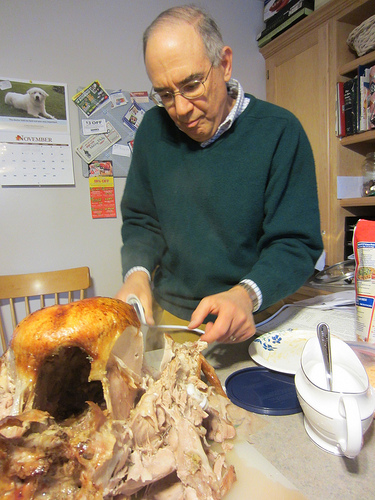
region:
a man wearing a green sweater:
[120, 5, 324, 359]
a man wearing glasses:
[117, 6, 322, 348]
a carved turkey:
[0, 295, 237, 497]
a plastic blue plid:
[225, 365, 303, 416]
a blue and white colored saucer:
[247, 328, 324, 376]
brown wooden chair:
[0, 267, 91, 351]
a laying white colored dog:
[3, 86, 56, 119]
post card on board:
[71, 68, 109, 119]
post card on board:
[80, 115, 108, 133]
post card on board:
[109, 91, 132, 113]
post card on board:
[128, 82, 151, 105]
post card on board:
[122, 104, 145, 127]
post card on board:
[114, 137, 138, 158]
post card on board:
[92, 152, 119, 223]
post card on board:
[86, 126, 116, 164]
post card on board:
[110, 147, 135, 163]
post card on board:
[125, 140, 138, 153]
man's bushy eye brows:
[165, 67, 223, 92]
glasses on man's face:
[138, 76, 221, 112]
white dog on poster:
[4, 84, 56, 111]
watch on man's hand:
[231, 278, 269, 319]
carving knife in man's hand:
[112, 283, 160, 341]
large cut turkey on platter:
[17, 296, 218, 482]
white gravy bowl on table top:
[297, 325, 369, 461]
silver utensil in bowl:
[307, 321, 337, 389]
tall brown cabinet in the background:
[275, 29, 345, 104]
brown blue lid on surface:
[229, 365, 300, 424]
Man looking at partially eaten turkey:
[0, 6, 323, 498]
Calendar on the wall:
[0, 76, 75, 189]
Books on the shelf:
[336, 65, 373, 140]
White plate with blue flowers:
[249, 325, 309, 373]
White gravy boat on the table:
[293, 327, 372, 463]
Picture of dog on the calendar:
[0, 84, 59, 119]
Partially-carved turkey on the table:
[2, 296, 239, 497]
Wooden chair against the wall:
[0, 264, 93, 346]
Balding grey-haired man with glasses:
[141, 3, 234, 145]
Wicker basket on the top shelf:
[345, 18, 373, 56]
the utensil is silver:
[318, 320, 335, 393]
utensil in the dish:
[301, 327, 367, 475]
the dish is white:
[297, 375, 365, 460]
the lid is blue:
[233, 373, 291, 429]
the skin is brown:
[31, 305, 113, 368]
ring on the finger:
[227, 335, 235, 342]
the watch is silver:
[238, 279, 253, 312]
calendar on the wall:
[1, 73, 65, 195]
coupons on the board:
[78, 85, 144, 182]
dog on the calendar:
[6, 83, 65, 121]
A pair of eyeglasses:
[143, 45, 219, 110]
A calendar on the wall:
[0, 71, 79, 191]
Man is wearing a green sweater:
[110, 0, 325, 347]